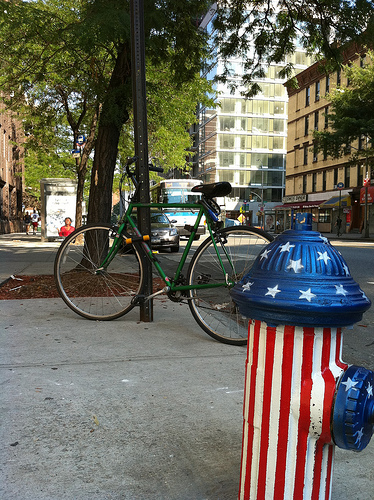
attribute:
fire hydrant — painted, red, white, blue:
[227, 212, 374, 499]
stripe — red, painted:
[273, 324, 296, 499]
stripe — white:
[249, 322, 269, 499]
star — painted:
[297, 288, 317, 302]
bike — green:
[53, 153, 276, 346]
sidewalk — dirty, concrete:
[0, 232, 374, 499]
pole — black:
[128, 0, 153, 323]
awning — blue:
[320, 194, 352, 210]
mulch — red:
[0, 273, 168, 300]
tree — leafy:
[57, 0, 156, 275]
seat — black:
[190, 180, 232, 196]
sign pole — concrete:
[39, 180, 47, 242]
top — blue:
[230, 212, 372, 327]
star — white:
[278, 240, 296, 254]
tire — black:
[52, 222, 146, 321]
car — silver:
[113, 212, 180, 257]